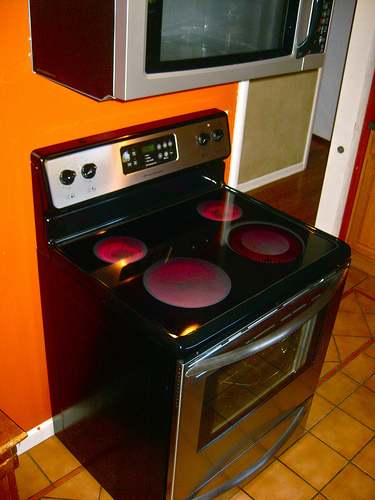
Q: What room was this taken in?
A: Kitchen.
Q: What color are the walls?
A: Orange.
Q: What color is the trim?
A: White.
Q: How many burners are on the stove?
A: Four.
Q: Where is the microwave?
A: Above the stove.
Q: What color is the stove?
A: Black.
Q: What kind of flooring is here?
A: Tile.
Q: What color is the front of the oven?
A: Stainless steel.